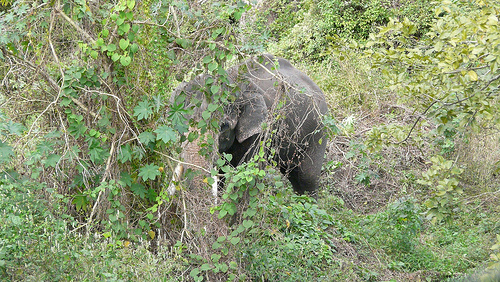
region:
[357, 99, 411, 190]
Green dry grass in the field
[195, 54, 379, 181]
A big grey elephant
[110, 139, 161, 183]
green small tree lives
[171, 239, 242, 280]
green small tree lives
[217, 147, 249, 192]
green small tree lives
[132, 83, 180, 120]
green small tree lives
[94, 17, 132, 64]
green small tree lives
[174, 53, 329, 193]
Grey elephant behind the trees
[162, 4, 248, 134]
Green leaves coming down over the elephant's face.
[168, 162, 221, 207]
Two white tusks on an elephant.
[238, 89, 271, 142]
Elephant's left grey ear.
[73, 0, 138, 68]
Light colored green leaves on the top that look like hearts.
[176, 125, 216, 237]
Long brown colored elephant trunk.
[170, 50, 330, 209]
A grey elephant with tusks behind the leaves and branches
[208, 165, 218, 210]
White left elephant tusk.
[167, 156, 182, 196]
Elephants right white elephant tusk.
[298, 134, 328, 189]
Back grey leg of an elephant.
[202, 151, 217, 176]
aprt of a tree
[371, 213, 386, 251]
part of a plant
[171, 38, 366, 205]
this is an elephant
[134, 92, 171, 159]
these are leaves on a branch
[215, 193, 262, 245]
these are leaves on a branch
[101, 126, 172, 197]
these are leaves on a branch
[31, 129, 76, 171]
these are leaves on a branch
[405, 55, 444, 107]
these are leaves on a branch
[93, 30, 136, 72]
these are leaves on a branch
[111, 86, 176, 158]
these are leaves on a branch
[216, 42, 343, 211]
an elephant standing in the woods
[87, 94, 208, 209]
leafless branch of a tree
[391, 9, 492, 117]
green leaves of a tree branch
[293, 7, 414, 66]
green bushes growing in the forest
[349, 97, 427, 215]
dead grey bush on the ground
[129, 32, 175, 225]
green vines growing on the tree trunk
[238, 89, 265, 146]
grey ear of the elephant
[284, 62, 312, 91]
grey skin of the elephant's back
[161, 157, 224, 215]
white tusks of the elephant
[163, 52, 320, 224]
Elephant behind dense bushes.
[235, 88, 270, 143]
Closest ear on an elephant.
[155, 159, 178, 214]
Tusk on an elephant to the left.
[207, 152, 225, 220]
Tusk on an elephant to the right.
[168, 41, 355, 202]
The back of the elephant.